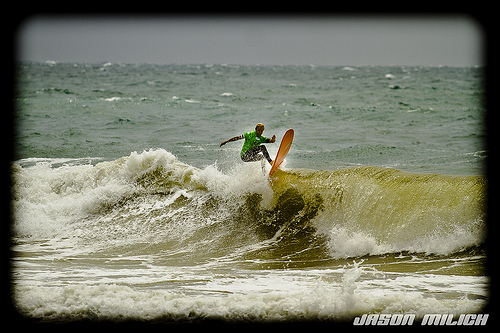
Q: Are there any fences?
A: No, there are no fences.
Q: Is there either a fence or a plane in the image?
A: No, there are no fences or airplanes.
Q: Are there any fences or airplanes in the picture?
A: No, there are no fences or airplanes.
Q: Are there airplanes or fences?
A: No, there are no fences or airplanes.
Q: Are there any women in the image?
A: No, there are no women.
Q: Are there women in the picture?
A: No, there are no women.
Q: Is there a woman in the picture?
A: No, there are no women.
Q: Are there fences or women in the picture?
A: No, there are no women or fences.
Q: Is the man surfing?
A: Yes, the man is surfing.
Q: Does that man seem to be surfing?
A: Yes, the man is surfing.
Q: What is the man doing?
A: The man is surfing.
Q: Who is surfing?
A: The man is surfing.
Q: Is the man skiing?
A: No, the man is surfing.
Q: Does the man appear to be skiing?
A: No, the man is surfing.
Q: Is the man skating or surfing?
A: The man is surfing.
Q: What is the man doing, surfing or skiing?
A: The man is surfing.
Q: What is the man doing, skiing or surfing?
A: The man is surfing.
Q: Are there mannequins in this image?
A: No, there are no mannequins.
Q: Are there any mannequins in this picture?
A: No, there are no mannequins.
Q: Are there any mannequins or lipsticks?
A: No, there are no mannequins or lipsticks.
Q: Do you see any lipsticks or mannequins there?
A: No, there are no mannequins or lipsticks.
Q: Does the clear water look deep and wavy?
A: Yes, the water is deep and wavy.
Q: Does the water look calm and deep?
A: No, the water is deep but wavy.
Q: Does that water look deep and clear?
A: Yes, the water is deep and clear.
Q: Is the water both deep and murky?
A: No, the water is deep but clear.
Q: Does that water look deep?
A: Yes, the water is deep.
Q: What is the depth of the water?
A: The water is deep.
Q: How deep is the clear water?
A: The water is deep.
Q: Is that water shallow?
A: No, the water is deep.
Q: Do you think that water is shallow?
A: No, the water is deep.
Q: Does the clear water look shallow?
A: No, the water is deep.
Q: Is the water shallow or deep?
A: The water is deep.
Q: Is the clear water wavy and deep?
A: Yes, the water is wavy and deep.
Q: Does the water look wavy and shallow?
A: No, the water is wavy but deep.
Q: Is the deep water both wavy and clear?
A: Yes, the water is wavy and clear.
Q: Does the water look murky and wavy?
A: No, the water is wavy but clear.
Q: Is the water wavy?
A: Yes, the water is wavy.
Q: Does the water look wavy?
A: Yes, the water is wavy.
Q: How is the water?
A: The water is wavy.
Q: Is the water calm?
A: No, the water is wavy.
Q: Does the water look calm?
A: No, the water is wavy.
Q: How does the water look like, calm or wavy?
A: The water is wavy.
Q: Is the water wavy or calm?
A: The water is wavy.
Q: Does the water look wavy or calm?
A: The water is wavy.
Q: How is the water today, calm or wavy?
A: The water is wavy.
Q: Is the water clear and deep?
A: Yes, the water is clear and deep.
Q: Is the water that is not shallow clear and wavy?
A: Yes, the water is clear and wavy.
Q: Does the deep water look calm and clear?
A: No, the water is clear but wavy.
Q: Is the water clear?
A: Yes, the water is clear.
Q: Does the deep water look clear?
A: Yes, the water is clear.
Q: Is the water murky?
A: No, the water is clear.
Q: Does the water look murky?
A: No, the water is clear.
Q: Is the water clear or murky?
A: The water is clear.